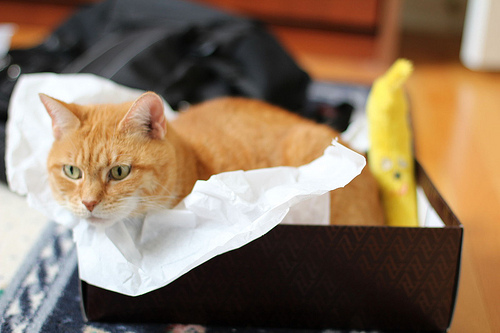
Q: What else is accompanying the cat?
A: Banana.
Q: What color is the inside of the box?
A: White.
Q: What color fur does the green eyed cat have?
A: Orange.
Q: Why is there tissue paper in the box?
A: Vegetables were wrapped.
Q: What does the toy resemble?
A: Banana.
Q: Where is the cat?
A: In a box.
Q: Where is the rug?
A: Under the box.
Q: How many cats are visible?
A: 1.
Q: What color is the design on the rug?
A: Blue.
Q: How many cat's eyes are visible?
A: 2.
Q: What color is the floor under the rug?
A: Brown.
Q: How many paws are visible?
A: 0.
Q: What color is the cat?
A: Orange.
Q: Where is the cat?
A: In a box.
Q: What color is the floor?
A: Tan.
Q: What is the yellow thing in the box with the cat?
A: Banana.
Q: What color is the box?
A: Brown.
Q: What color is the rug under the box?
A: Blue.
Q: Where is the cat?
A: In the box.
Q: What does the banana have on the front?
A: Face.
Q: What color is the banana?
A: Yellow.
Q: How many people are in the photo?
A: None.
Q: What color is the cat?
A: Orange.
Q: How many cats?
A: 1.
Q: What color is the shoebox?
A: Brown.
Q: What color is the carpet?
A: White and grey.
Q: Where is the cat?
A: Shoebox.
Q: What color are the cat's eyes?
A: Green.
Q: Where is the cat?
A: Box.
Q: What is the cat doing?
A: Sitting.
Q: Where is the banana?
A: Behind the cat.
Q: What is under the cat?
A: Tissue paper.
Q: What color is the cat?
A: Brownish orange.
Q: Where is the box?
A: On the floor.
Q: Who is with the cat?
A: No one.